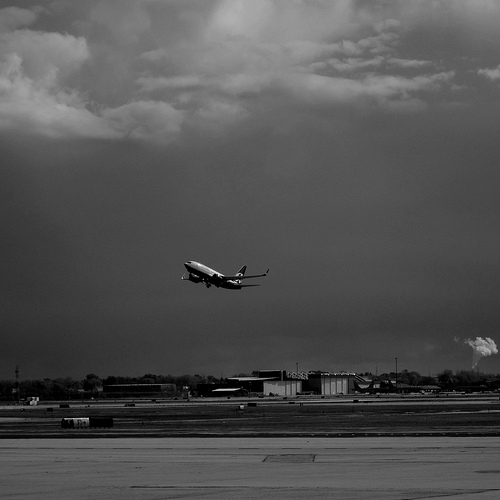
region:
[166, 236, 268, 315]
the plane is departing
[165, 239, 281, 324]
the plane is departing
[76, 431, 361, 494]
the runway is paved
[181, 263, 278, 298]
plane is in air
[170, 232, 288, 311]
plane is moving horizontaly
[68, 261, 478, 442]
view was taken at night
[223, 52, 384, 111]
sky is covered with clouds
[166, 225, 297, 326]
the plane is in motion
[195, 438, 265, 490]
the floor is clear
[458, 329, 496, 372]
smoke emitted from a nearby building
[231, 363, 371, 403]
bulidings are adjacent to the field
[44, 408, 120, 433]
the tank is blck and white in color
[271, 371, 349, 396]
the building walls are white in color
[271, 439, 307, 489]
part f a lid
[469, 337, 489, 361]
part fo a smoke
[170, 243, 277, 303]
plane flying in sky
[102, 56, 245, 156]
light white clouds in sky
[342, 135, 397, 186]
dark sky with light clouds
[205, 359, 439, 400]
several buildings on ground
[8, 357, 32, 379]
power tower in the sky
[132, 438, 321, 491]
pavement runway for plane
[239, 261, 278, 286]
fin of airplane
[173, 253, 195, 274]
cockpit of airplane in sky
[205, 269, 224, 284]
engine of airplane in sky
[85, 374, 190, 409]
building in front of trees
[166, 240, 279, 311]
a plane taking off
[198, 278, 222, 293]
some of the planes landing gear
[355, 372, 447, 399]
a plane that is grounded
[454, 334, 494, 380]
a big cloud of smoke or steam is in the background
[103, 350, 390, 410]
buildings are in the background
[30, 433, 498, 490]
one of the planes runways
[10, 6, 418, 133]
clouds are in the sky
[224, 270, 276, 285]
one of the planes wings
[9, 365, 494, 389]
many trees are in the background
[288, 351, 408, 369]
a few power lines in the distance